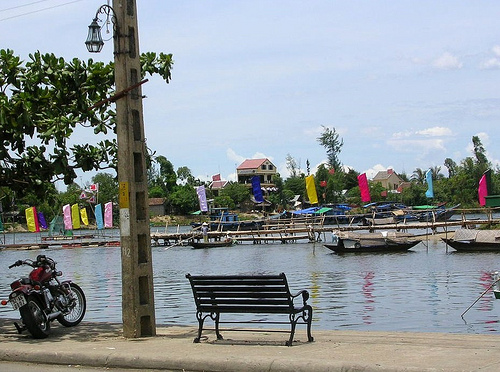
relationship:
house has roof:
[215, 139, 315, 225] [239, 160, 261, 167]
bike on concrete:
[0, 253, 86, 339] [1, 317, 498, 370]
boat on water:
[184, 237, 232, 247] [1, 213, 497, 329]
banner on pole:
[357, 172, 371, 202] [363, 169, 372, 209]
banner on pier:
[357, 172, 371, 202] [14, 220, 499, 253]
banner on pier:
[305, 174, 319, 205] [263, 204, 370, 223]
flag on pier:
[13, 201, 58, 243] [3, 205, 198, 232]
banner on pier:
[62, 204, 72, 230] [5, 210, 493, 251]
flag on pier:
[25, 206, 41, 233] [2, 212, 490, 245]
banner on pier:
[104, 201, 113, 229] [212, 209, 469, 238]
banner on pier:
[478, 174, 488, 207] [0, 216, 485, 252]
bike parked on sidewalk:
[0, 253, 86, 339] [0, 316, 497, 370]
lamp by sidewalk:
[84, 4, 119, 60] [0, 316, 497, 370]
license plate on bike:
[10, 293, 28, 311] [21, 274, 109, 316]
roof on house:
[362, 141, 421, 188] [371, 135, 468, 218]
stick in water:
[460, 272, 496, 312] [2, 246, 499, 326]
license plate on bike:
[10, 287, 51, 319] [2, 247, 86, 337]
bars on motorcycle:
[7, 247, 52, 272] [16, 231, 86, 342]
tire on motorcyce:
[55, 282, 86, 324] [3, 254, 88, 339]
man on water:
[189, 225, 211, 244] [1, 213, 497, 329]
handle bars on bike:
[7, 255, 59, 272] [2, 255, 86, 339]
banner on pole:
[357, 172, 371, 202] [67, 200, 74, 240]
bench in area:
[180, 269, 315, 345] [4, 230, 484, 324]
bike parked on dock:
[0, 253, 86, 339] [2, 210, 484, 253]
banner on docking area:
[475, 173, 490, 208] [1, 205, 498, 254]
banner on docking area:
[420, 169, 437, 199] [1, 205, 498, 254]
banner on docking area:
[354, 171, 372, 203] [1, 205, 498, 254]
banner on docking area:
[302, 172, 321, 204] [1, 205, 498, 254]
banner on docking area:
[246, 175, 266, 205] [1, 205, 498, 254]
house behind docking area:
[208, 157, 278, 214] [159, 199, 493, 251]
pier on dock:
[0, 216, 485, 252] [21, 215, 496, 249]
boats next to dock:
[327, 211, 498, 256] [152, 211, 497, 243]